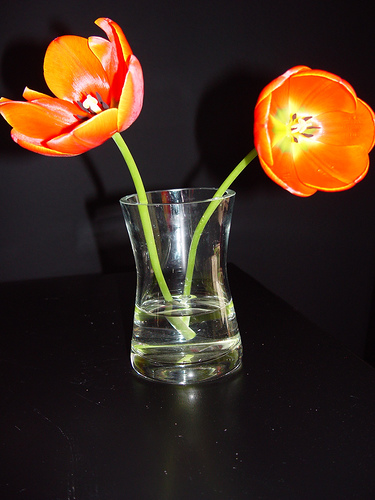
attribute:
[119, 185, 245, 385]
vase — glass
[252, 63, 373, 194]
flower — orange